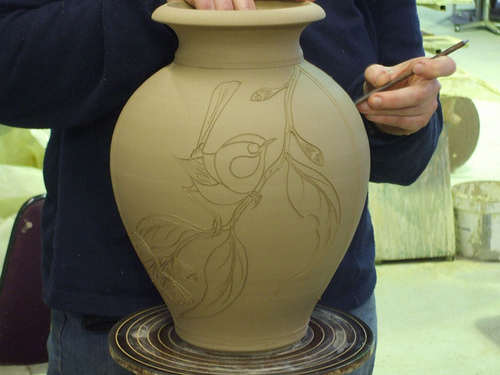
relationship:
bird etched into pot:
[174, 133, 278, 209] [106, 2, 378, 354]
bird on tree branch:
[174, 133, 278, 209] [131, 61, 342, 318]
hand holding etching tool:
[360, 51, 456, 138] [353, 36, 470, 106]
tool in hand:
[352, 38, 472, 106] [359, 48, 459, 135]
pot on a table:
[108, 2, 370, 354] [108, 302, 374, 374]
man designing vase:
[1, 1, 456, 373] [107, 1, 373, 350]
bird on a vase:
[173, 135, 275, 234] [107, 1, 373, 350]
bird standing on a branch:
[174, 133, 278, 209] [122, 63, 327, 322]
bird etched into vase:
[174, 133, 278, 209] [107, 1, 373, 350]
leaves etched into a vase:
[147, 215, 251, 330] [135, 0, 349, 350]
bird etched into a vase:
[174, 133, 278, 209] [107, 1, 373, 350]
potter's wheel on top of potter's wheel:
[104, 302, 372, 375] [107, 302, 372, 372]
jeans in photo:
[47, 291, 374, 373] [4, 3, 496, 372]